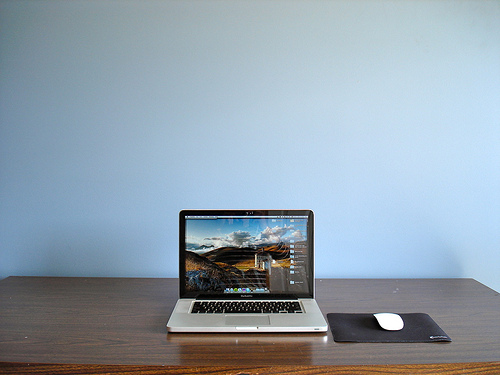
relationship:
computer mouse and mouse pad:
[373, 312, 405, 331] [328, 312, 451, 341]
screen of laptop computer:
[184, 214, 309, 291] [167, 208, 329, 334]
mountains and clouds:
[187, 245, 290, 269] [189, 222, 296, 246]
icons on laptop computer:
[224, 286, 269, 295] [167, 208, 329, 334]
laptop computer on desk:
[167, 208, 329, 334] [0, 280, 499, 372]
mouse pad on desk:
[328, 312, 451, 341] [0, 280, 499, 372]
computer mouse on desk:
[373, 312, 405, 331] [0, 280, 499, 372]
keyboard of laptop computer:
[167, 295, 328, 332] [167, 208, 329, 334]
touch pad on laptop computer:
[227, 313, 272, 329] [167, 208, 329, 334]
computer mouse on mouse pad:
[373, 312, 405, 331] [328, 312, 451, 341]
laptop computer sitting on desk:
[167, 208, 329, 334] [0, 280, 499, 372]